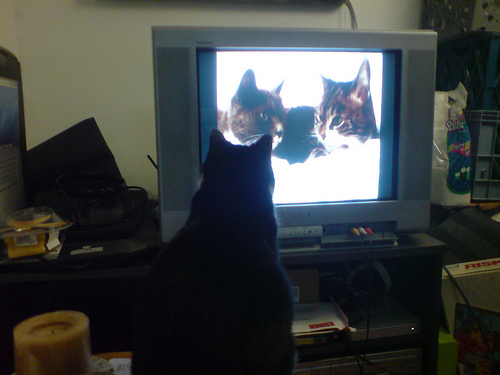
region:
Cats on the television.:
[226, 88, 378, 165]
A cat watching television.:
[173, 118, 297, 343]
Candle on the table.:
[17, 310, 86, 373]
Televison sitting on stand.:
[136, 7, 439, 247]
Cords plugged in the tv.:
[327, 213, 389, 253]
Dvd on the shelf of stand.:
[325, 292, 423, 352]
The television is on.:
[190, 48, 433, 236]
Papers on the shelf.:
[292, 293, 345, 337]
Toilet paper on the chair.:
[443, 90, 473, 218]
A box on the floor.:
[453, 255, 498, 332]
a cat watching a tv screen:
[132, 129, 324, 355]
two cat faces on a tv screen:
[232, 68, 373, 156]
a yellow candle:
[15, 311, 105, 363]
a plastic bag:
[430, 82, 480, 216]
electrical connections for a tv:
[347, 221, 381, 243]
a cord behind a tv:
[334, 2, 368, 34]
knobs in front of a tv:
[280, 220, 330, 246]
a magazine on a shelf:
[278, 288, 358, 352]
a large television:
[127, 20, 458, 274]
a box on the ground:
[435, 252, 498, 309]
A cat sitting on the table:
[130, 130, 315, 372]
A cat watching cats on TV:
[130, 60, 305, 370]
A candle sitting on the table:
[11, 302, 88, 369]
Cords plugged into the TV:
[341, 219, 390, 370]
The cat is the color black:
[156, 150, 280, 366]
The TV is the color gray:
[136, 15, 453, 236]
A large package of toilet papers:
[432, 81, 473, 210]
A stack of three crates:
[411, 2, 499, 211]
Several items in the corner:
[423, 198, 498, 371]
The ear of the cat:
[248, 126, 278, 159]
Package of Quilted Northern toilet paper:
[432, 83, 473, 209]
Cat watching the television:
[130, 25, 439, 373]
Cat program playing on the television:
[149, 23, 434, 248]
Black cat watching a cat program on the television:
[117, 23, 437, 373]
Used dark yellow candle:
[10, 308, 90, 374]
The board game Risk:
[442, 255, 498, 333]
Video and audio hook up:
[347, 224, 377, 374]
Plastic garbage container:
[0, 205, 73, 265]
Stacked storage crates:
[419, 0, 499, 205]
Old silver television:
[148, 24, 433, 259]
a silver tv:
[137, 10, 447, 237]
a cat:
[135, 110, 382, 373]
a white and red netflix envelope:
[271, 286, 381, 360]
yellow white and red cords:
[334, 218, 406, 269]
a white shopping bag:
[396, 50, 475, 220]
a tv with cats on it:
[132, 14, 477, 272]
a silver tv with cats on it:
[127, 13, 487, 269]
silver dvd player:
[269, 285, 434, 374]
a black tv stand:
[168, 205, 470, 366]